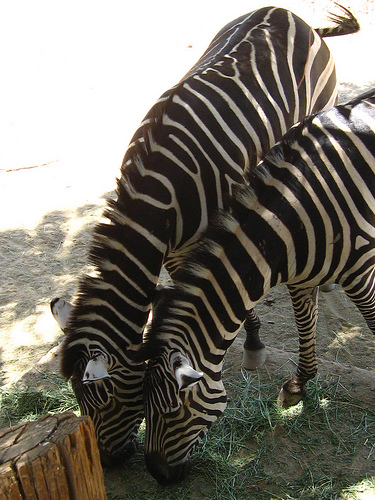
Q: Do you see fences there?
A: No, there are no fences.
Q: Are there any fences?
A: No, there are no fences.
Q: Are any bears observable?
A: No, there are no bears.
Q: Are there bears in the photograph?
A: No, there are no bears.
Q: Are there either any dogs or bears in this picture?
A: No, there are no bears or dogs.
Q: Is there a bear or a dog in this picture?
A: No, there are no bears or dogs.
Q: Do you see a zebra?
A: Yes, there is a zebra.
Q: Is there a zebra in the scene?
A: Yes, there is a zebra.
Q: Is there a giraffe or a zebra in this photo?
A: Yes, there is a zebra.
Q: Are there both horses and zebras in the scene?
A: No, there is a zebra but no horses.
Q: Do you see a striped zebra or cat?
A: Yes, there is a striped zebra.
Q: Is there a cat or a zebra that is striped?
A: Yes, the zebra is striped.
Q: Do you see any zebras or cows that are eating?
A: Yes, the zebra is eating.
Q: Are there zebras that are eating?
A: Yes, there is a zebra that is eating.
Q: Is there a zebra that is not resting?
A: Yes, there is a zebra that is eating.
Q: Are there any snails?
A: No, there are no snails.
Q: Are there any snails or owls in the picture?
A: No, there are no snails or owls.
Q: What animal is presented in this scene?
A: The animal is a zebra.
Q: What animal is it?
A: The animal is a zebra.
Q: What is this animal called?
A: This is a zebra.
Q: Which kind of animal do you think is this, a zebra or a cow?
A: This is a zebra.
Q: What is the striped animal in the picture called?
A: The animal is a zebra.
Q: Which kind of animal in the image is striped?
A: The animal is a zebra.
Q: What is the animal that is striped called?
A: The animal is a zebra.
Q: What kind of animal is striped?
A: The animal is a zebra.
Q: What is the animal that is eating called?
A: The animal is a zebra.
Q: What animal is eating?
A: The animal is a zebra.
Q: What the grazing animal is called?
A: The animal is a zebra.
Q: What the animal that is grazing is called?
A: The animal is a zebra.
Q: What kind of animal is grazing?
A: The animal is a zebra.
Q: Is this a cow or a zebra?
A: This is a zebra.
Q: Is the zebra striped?
A: Yes, the zebra is striped.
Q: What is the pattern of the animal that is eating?
A: The zebra is striped.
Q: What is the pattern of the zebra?
A: The zebra is striped.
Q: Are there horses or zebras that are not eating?
A: No, there is a zebra but it is eating.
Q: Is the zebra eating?
A: Yes, the zebra is eating.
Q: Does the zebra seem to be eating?
A: Yes, the zebra is eating.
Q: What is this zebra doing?
A: The zebra is eating.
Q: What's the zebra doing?
A: The zebra is eating.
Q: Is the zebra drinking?
A: No, the zebra is eating.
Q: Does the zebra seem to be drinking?
A: No, the zebra is eating.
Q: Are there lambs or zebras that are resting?
A: No, there is a zebra but it is eating.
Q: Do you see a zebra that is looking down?
A: No, there is a zebra but it is eating.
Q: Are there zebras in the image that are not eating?
A: No, there is a zebra but it is eating.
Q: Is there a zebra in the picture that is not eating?
A: No, there is a zebra but it is eating.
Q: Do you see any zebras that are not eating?
A: No, there is a zebra but it is eating.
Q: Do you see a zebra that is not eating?
A: No, there is a zebra but it is eating.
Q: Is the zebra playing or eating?
A: The zebra is eating.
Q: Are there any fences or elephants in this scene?
A: No, there are no fences or elephants.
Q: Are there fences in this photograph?
A: No, there are no fences.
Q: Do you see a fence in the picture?
A: No, there are no fences.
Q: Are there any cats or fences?
A: No, there are no fences or cats.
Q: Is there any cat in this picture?
A: No, there are no cats.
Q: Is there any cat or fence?
A: No, there are no cats or fences.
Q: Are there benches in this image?
A: No, there are no benches.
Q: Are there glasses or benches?
A: No, there are no benches or glasses.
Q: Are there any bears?
A: No, there are no bears.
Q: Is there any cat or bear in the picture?
A: No, there are no bears or cats.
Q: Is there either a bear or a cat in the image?
A: No, there are no bears or cats.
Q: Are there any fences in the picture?
A: No, there are no fences.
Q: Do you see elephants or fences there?
A: No, there are no fences or elephants.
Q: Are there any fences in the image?
A: No, there are no fences.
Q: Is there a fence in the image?
A: No, there are no fences.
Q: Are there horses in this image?
A: No, there are no horses.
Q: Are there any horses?
A: No, there are no horses.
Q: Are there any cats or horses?
A: No, there are no horses or cats.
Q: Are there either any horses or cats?
A: No, there are no horses or cats.